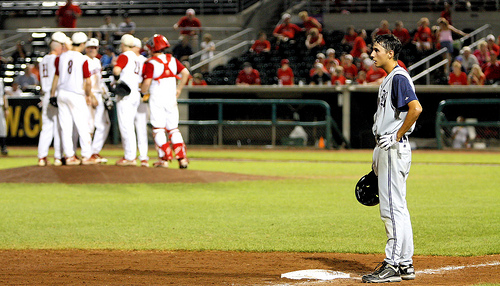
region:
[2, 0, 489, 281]
A night time baseball game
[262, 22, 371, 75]
spectators all wearing red shirts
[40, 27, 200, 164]
a group of players discuss things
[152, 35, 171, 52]
a red batting helmet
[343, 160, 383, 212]
a black batters helmet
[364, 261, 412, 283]
grey black and white nike shoes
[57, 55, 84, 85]
the number 8 on a players shirt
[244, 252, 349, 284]
a white plate on the ground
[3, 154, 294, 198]
this is the pitchers mound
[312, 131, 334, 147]
an orange safety cone in the background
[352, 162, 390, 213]
he is holding his helmet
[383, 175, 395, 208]
the line is dark gray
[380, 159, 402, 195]
the pants are light gray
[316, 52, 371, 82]
they are watching the event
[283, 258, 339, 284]
the plate is white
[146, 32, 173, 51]
the helmet is red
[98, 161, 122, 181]
the mound is brown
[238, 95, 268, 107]
the pole is green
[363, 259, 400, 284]
his shoes are black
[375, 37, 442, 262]
Baseball player standing on field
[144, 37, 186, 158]
Baseball player standing on field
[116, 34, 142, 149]
Baseball player standing on field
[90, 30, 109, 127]
Baseball player standing on field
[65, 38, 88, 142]
Baseball player standing on field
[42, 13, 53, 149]
Baseball player standing on field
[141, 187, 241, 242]
short green grass on field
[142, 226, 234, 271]
red clay on baseball field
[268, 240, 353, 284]
white plate on baseball field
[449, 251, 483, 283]
white line painted on field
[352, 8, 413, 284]
baseball player standing on field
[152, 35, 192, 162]
baseball player standing on field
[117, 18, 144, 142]
baseball player standing on field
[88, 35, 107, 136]
baseball player standing on field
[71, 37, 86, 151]
baseball player standing on field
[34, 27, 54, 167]
baseball player standing on field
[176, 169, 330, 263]
green grass on baseball field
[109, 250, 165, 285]
red clay on baseball field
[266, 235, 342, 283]
whit plate on baseball field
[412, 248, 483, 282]
white lines on baseball field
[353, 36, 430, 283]
a baseball player waiting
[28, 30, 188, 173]
men in hats standing on the mound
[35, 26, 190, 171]
players deliberating with each other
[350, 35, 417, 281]
a man wearing a baseball uniform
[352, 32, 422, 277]
a baseball player holding a helmet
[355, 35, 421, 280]
a baseball player wearing Nike shoes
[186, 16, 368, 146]
the crowd watching in the distance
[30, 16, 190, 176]
baseball players standing on the mound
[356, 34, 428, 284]
a sweaty baseball player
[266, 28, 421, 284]
a baseball player standing besides first plate